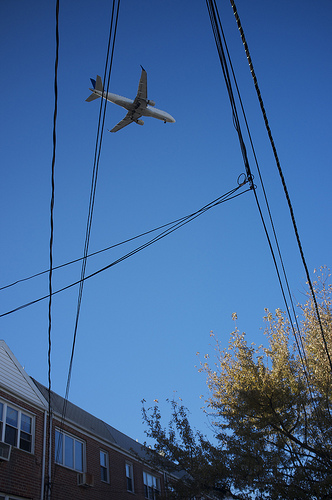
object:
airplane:
[85, 67, 174, 136]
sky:
[2, 0, 331, 499]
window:
[55, 425, 88, 476]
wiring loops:
[237, 171, 246, 186]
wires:
[229, 2, 332, 372]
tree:
[128, 267, 331, 497]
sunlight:
[196, 265, 332, 444]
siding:
[0, 337, 52, 408]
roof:
[30, 378, 201, 485]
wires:
[44, 1, 64, 418]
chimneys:
[136, 438, 139, 442]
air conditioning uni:
[76, 468, 96, 489]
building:
[3, 343, 222, 499]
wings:
[108, 112, 134, 133]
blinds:
[3, 404, 34, 433]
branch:
[277, 410, 331, 453]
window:
[143, 468, 159, 488]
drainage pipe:
[40, 408, 48, 500]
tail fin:
[91, 76, 101, 94]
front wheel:
[163, 119, 171, 129]